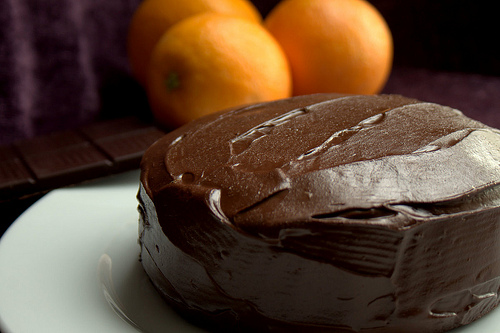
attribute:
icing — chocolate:
[127, 84, 497, 330]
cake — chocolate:
[135, 84, 497, 331]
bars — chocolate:
[1, 115, 141, 187]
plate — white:
[2, 89, 497, 329]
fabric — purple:
[0, 0, 94, 144]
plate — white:
[1, 169, 499, 331]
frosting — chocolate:
[306, 107, 498, 209]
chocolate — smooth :
[26, 97, 141, 167]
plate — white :
[22, 164, 136, 330]